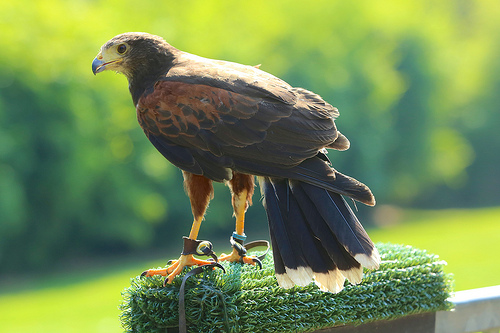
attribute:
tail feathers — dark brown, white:
[271, 160, 382, 294]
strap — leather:
[184, 235, 208, 259]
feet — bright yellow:
[150, 217, 280, 269]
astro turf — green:
[133, 233, 460, 331]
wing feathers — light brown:
[139, 80, 269, 149]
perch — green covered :
[120, 236, 463, 326]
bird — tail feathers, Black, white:
[80, 28, 395, 306]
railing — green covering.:
[396, 315, 443, 325]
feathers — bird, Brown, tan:
[260, 166, 392, 298]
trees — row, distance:
[5, 2, 478, 285]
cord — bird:
[182, 232, 258, 271]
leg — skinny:
[190, 199, 255, 252]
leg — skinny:
[182, 188, 253, 250]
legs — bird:
[172, 183, 255, 261]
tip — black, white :
[274, 250, 379, 295]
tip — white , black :
[265, 249, 384, 300]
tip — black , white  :
[274, 250, 389, 294]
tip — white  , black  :
[268, 253, 397, 295]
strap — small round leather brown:
[179, 235, 203, 258]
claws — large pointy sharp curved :
[144, 253, 214, 293]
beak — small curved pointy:
[88, 55, 109, 75]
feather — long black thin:
[273, 163, 371, 220]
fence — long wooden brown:
[444, 290, 484, 325]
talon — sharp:
[138, 256, 177, 281]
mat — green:
[125, 240, 448, 331]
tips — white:
[273, 241, 380, 297]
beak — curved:
[90, 54, 101, 72]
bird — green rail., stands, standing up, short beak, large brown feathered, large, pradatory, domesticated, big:
[90, 32, 384, 299]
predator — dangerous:
[91, 27, 385, 291]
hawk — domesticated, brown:
[86, 27, 385, 297]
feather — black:
[289, 156, 379, 210]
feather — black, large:
[303, 182, 379, 270]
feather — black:
[325, 188, 381, 261]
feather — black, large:
[279, 174, 368, 285]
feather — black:
[257, 172, 316, 286]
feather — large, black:
[253, 172, 294, 286]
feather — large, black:
[262, 171, 313, 289]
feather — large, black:
[297, 178, 381, 273]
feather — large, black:
[327, 189, 387, 261]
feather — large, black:
[330, 180, 384, 270]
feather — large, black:
[267, 171, 347, 294]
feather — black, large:
[290, 153, 384, 209]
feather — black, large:
[251, 172, 297, 292]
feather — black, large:
[262, 174, 316, 292]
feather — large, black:
[256, 171, 295, 294]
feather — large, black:
[284, 159, 376, 207]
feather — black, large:
[267, 172, 313, 291]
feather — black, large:
[281, 178, 344, 295]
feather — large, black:
[278, 178, 347, 292]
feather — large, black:
[283, 177, 367, 288]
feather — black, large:
[259, 177, 319, 288]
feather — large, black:
[273, 170, 364, 286]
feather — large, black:
[298, 183, 382, 270]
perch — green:
[119, 238, 449, 330]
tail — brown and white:
[262, 148, 379, 297]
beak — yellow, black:
[81, 54, 110, 74]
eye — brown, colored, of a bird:
[108, 39, 130, 54]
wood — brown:
[383, 314, 411, 327]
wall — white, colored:
[443, 281, 494, 329]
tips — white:
[278, 256, 405, 295]